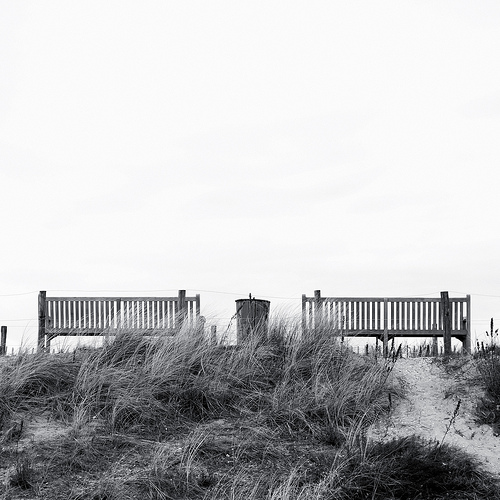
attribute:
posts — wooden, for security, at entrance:
[305, 292, 453, 353]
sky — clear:
[5, 10, 495, 360]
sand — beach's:
[360, 346, 497, 475]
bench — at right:
[314, 276, 479, 343]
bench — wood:
[27, 285, 221, 362]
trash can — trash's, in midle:
[234, 289, 272, 346]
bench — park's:
[273, 243, 498, 396]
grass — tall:
[2, 313, 400, 499]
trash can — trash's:
[244, 298, 284, 348]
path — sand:
[366, 354, 497, 479]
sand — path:
[369, 357, 499, 476]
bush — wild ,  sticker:
[474, 337, 495, 410]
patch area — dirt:
[396, 353, 463, 438]